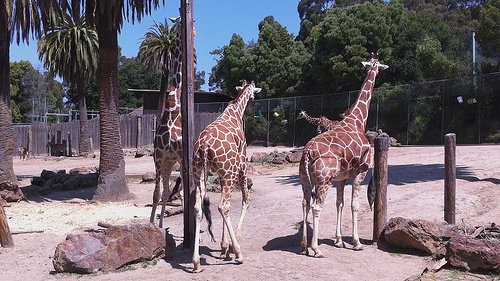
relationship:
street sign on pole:
[248, 105, 273, 121] [255, 107, 279, 151]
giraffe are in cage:
[299, 52, 389, 259] [9, 56, 499, 279]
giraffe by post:
[284, 46, 393, 257] [364, 123, 397, 246]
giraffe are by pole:
[299, 52, 389, 259] [172, 0, 212, 273]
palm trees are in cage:
[9, 8, 203, 222] [9, 56, 499, 279]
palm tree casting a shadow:
[64, 3, 147, 217] [23, 160, 109, 199]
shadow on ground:
[23, 160, 109, 199] [7, 147, 497, 277]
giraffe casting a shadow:
[284, 46, 393, 257] [271, 206, 354, 259]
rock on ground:
[38, 193, 190, 279] [7, 147, 497, 277]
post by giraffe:
[364, 123, 397, 246] [284, 46, 393, 257]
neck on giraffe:
[347, 72, 388, 126] [284, 46, 393, 257]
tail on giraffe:
[300, 159, 320, 207] [284, 46, 393, 257]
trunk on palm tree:
[95, 23, 145, 198] [64, 3, 147, 217]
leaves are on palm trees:
[22, 0, 106, 84] [9, 8, 203, 222]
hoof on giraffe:
[328, 227, 348, 257] [284, 46, 393, 257]